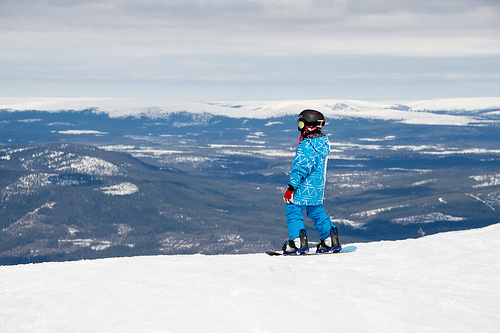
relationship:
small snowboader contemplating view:
[270, 106, 352, 258] [9, 121, 241, 192]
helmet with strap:
[299, 105, 324, 135] [303, 130, 316, 138]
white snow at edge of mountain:
[0, 220, 499, 332] [0, 217, 497, 331]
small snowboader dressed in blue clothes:
[265, 106, 352, 270] [281, 137, 337, 237]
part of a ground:
[271, 261, 331, 309] [2, 218, 498, 328]